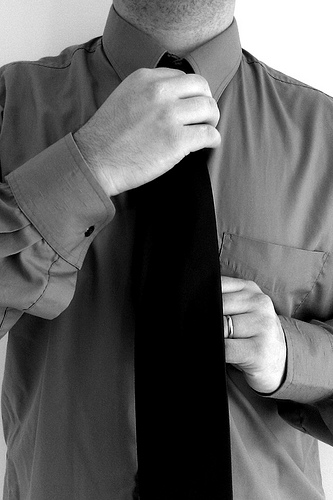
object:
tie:
[134, 55, 234, 500]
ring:
[227, 315, 234, 339]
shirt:
[0, 5, 332, 500]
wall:
[0, 0, 333, 98]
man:
[0, 0, 333, 500]